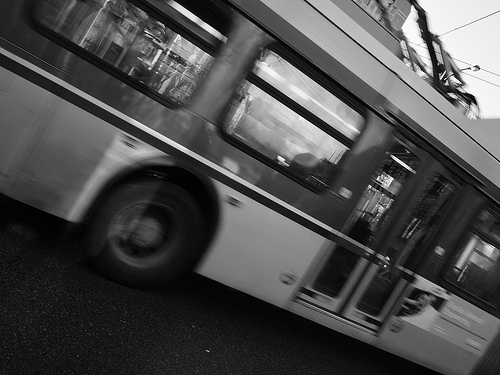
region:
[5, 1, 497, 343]
a black and white photo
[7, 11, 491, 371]
a scene outside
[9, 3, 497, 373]
a photo of a bus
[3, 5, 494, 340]
a white bus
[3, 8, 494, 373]
a scene during the day time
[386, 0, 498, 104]
power lines in the sky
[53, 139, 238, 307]
a wheel to the bus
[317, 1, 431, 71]
a building behind the bus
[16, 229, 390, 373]
a street under the bus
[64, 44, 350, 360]
a bus on the road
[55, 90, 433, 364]
a bus on the street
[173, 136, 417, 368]
a road with a bus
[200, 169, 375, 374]
a street with a bus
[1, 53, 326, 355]
a passenger bus on teh road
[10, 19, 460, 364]
a passenger bus on the street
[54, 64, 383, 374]
a street with a bus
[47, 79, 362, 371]
a road with a bus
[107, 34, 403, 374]
a large bus on the road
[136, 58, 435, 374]
a large bus on the street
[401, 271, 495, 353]
a billboard on the side of a bus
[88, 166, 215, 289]
large rubber bus tire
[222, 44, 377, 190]
a window on the bus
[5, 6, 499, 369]
side of a bus driving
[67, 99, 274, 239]
reflection on the side of the bus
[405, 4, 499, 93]
wires in the sky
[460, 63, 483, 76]
lamp post in the air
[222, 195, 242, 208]
light on the side of the bus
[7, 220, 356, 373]
asphalt covering the ground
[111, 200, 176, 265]
rims of the bus tire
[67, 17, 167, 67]
window of a bus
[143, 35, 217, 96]
window of a bus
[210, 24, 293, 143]
window of a bus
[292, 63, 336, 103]
window of a bus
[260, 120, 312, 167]
window of a bus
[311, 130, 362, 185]
window of a bus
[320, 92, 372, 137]
window of a bus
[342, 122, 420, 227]
window of a bus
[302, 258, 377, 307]
window of a bus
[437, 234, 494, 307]
window of a bus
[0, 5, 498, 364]
the picture is black and white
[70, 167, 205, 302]
the tire is black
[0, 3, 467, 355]
the bus is in motion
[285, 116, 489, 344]
the doors are closed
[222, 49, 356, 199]
the window is reflecting objects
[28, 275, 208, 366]
the street is black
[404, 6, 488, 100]
wires above the street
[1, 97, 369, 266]
a stripe on the bus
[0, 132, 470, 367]
the bottom half of the bus is light colored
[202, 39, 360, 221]
the window is closed